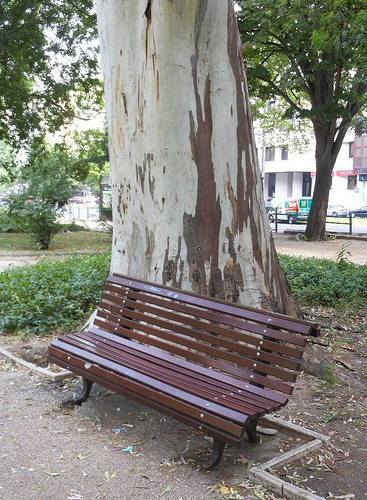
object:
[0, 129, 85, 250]
bush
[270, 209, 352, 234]
fence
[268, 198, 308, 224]
van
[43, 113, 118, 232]
building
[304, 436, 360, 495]
leaves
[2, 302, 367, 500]
ground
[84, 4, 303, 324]
tree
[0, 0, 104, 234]
tree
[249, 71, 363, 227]
building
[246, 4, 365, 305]
tree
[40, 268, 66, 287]
leaves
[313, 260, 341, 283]
leaves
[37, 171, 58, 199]
leaves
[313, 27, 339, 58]
leaves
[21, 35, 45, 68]
leaves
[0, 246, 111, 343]
grass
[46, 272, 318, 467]
bench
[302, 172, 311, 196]
window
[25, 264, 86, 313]
leaves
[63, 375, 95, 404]
black metal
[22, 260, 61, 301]
leaves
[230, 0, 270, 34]
leaves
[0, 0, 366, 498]
park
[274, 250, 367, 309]
greenery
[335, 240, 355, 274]
plants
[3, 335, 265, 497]
walkway